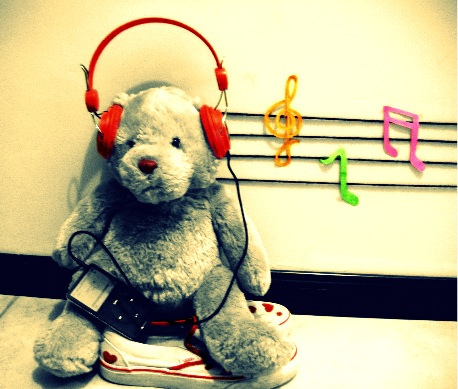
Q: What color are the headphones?
A: Orange.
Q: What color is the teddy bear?
A: Gray.